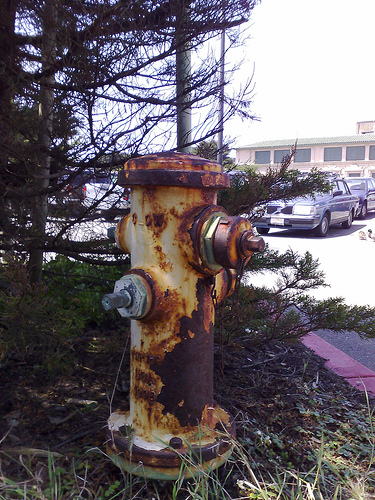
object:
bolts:
[120, 424, 229, 449]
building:
[229, 125, 373, 177]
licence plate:
[269, 215, 286, 227]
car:
[249, 174, 359, 236]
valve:
[202, 207, 265, 274]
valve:
[100, 270, 150, 319]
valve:
[102, 213, 133, 252]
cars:
[249, 171, 373, 237]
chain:
[210, 276, 240, 379]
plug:
[205, 215, 267, 271]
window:
[253, 150, 309, 165]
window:
[322, 145, 345, 161]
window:
[345, 144, 365, 162]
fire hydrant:
[101, 146, 270, 493]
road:
[60, 184, 374, 276]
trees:
[4, 1, 226, 178]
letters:
[130, 347, 165, 414]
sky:
[235, 20, 361, 125]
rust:
[169, 300, 210, 345]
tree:
[2, 3, 267, 380]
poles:
[169, 4, 202, 152]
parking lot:
[82, 154, 372, 296]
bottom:
[105, 408, 234, 482]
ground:
[4, 285, 360, 497]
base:
[105, 398, 242, 477]